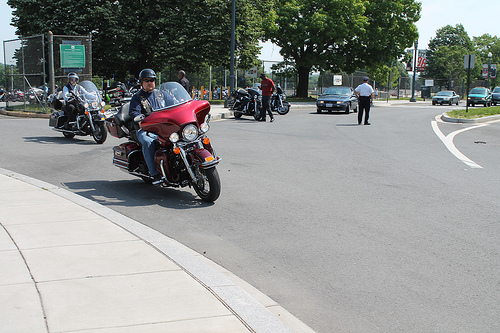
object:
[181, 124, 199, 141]
headlight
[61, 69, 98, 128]
man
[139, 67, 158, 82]
helmet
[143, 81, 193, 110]
window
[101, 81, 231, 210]
motor cycle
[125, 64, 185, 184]
man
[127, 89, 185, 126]
shirt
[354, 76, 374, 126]
person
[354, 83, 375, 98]
shirt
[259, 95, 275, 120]
pants.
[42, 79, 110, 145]
black motorcycle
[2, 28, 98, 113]
fencing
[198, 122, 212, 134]
light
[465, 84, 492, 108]
van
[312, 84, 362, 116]
black car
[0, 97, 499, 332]
street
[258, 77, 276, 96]
shirt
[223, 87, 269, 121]
motorcycle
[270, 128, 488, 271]
floor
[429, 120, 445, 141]
white line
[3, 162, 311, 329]
sidewalk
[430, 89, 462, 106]
car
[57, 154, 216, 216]
shadow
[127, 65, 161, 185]
person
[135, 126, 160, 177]
blue jeans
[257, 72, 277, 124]
person